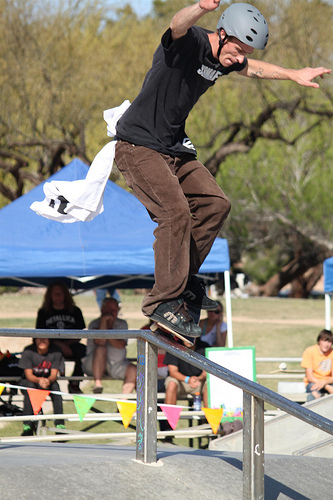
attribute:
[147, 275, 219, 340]
shoes — brown, black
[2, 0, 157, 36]
sky — blue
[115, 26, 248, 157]
t-shirt — black, white, cotton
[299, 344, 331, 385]
shirt — orange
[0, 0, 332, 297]
trees — green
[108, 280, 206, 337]
sneakers — black , tan 